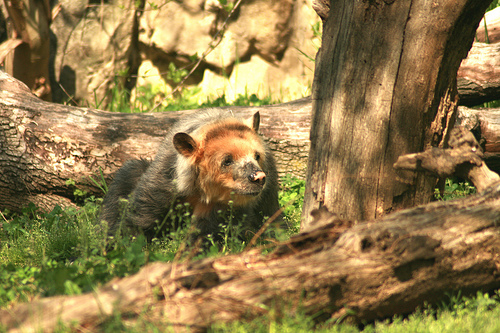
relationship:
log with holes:
[13, 187, 497, 331] [357, 227, 437, 281]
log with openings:
[13, 187, 497, 331] [252, 222, 348, 269]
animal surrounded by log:
[102, 108, 288, 245] [150, 217, 467, 324]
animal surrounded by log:
[102, 108, 288, 245] [3, 64, 221, 197]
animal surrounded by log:
[102, 108, 288, 245] [294, 2, 445, 217]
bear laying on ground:
[95, 103, 292, 259] [0, 68, 500, 330]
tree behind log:
[324, 2, 466, 207] [322, 218, 467, 317]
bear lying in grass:
[95, 108, 290, 255] [17, 216, 107, 276]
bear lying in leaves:
[95, 108, 290, 255] [44, 207, 124, 259]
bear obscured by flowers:
[95, 108, 290, 255] [164, 202, 193, 225]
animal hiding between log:
[102, 105, 285, 245] [13, 187, 497, 331]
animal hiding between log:
[102, 105, 285, 245] [0, 67, 500, 215]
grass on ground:
[414, 277, 486, 317] [41, 211, 113, 255]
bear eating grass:
[95, 108, 290, 255] [104, 224, 209, 296]